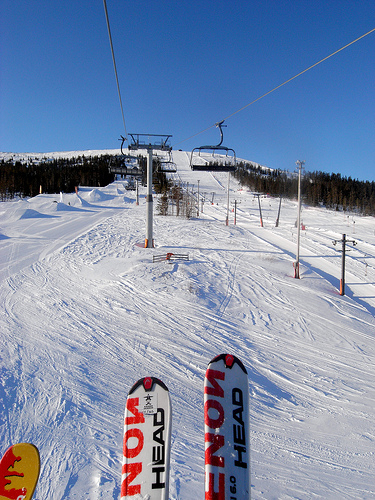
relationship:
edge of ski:
[152, 402, 168, 492] [115, 371, 183, 488]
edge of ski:
[233, 379, 245, 464] [208, 350, 248, 491]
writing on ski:
[122, 392, 171, 490] [115, 371, 183, 488]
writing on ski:
[212, 357, 249, 483] [208, 350, 248, 491]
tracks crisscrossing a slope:
[28, 219, 283, 414] [15, 160, 343, 467]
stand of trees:
[3, 151, 163, 200] [1, 146, 146, 203]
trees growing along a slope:
[223, 165, 363, 207] [15, 137, 347, 361]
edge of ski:
[2, 436, 49, 489] [7, 437, 45, 487]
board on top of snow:
[202, 347, 254, 490] [13, 201, 345, 477]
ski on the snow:
[109, 375, 174, 491] [13, 201, 345, 477]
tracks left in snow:
[28, 219, 283, 414] [10, 184, 357, 487]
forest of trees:
[222, 160, 363, 216] [203, 155, 363, 213]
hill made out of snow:
[87, 186, 110, 198] [6, 209, 346, 461]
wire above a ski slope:
[182, 29, 363, 149] [8, 147, 357, 480]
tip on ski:
[207, 353, 247, 374] [203, 351, 250, 497]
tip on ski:
[127, 376, 168, 393] [120, 375, 171, 497]